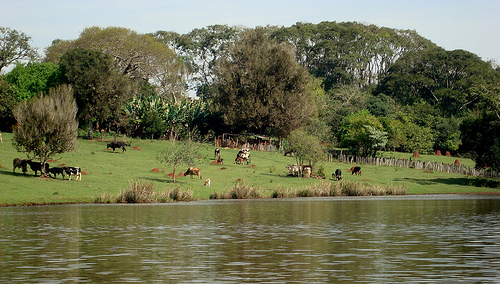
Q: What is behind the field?
A: Trees.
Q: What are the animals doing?
A: Grazing.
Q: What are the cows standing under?
A: Trees.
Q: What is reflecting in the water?
A: Light.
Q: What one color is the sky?
A: Blue.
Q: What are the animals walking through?
A: Grass.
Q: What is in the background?
A: Trees.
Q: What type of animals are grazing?
A: Cows.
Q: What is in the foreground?
A: Water.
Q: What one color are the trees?
A: Green.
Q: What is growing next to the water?
A: Bushes.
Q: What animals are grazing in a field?
A: Cows.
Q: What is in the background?
A: Trees.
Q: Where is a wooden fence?
A: On the right.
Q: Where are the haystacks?
A: In the field.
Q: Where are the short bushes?
A: Alongside the water.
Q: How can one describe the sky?
A: Light blue.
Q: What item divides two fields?
A: Wooden fence.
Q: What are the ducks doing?
A: There are no ducks.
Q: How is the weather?
A: Fair.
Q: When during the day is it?
A: Afternoon.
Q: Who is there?
A: No one.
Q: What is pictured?
A: Cows grazing.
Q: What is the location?
A: Farmland.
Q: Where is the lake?
A: Foreground.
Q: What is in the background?
A: Trees.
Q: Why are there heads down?
A: Grazing.